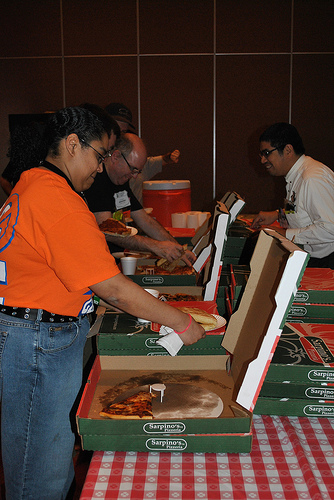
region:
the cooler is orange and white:
[140, 171, 192, 225]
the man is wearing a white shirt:
[256, 118, 332, 259]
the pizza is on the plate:
[96, 215, 138, 239]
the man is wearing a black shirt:
[81, 134, 198, 269]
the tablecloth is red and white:
[74, 408, 332, 498]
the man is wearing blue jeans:
[1, 299, 95, 498]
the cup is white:
[118, 252, 140, 276]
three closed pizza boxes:
[248, 317, 331, 425]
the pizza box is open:
[63, 222, 311, 433]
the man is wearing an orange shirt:
[1, 165, 121, 322]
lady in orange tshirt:
[11, 91, 118, 324]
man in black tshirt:
[98, 131, 166, 228]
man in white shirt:
[252, 113, 333, 261]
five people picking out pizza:
[12, 83, 331, 426]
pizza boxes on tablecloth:
[103, 364, 301, 498]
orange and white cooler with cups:
[140, 176, 215, 233]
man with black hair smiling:
[239, 118, 310, 175]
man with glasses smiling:
[111, 130, 158, 190]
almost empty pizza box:
[104, 366, 244, 453]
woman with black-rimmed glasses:
[25, 104, 118, 192]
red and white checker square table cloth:
[132, 458, 236, 485]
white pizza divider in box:
[143, 379, 175, 400]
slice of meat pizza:
[103, 384, 168, 423]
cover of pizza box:
[222, 224, 313, 406]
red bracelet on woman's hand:
[170, 313, 202, 338]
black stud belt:
[2, 297, 86, 332]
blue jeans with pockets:
[0, 317, 85, 496]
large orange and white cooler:
[142, 169, 199, 228]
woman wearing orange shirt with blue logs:
[1, 158, 116, 311]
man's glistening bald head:
[118, 130, 159, 166]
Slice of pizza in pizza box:
[99, 390, 154, 418]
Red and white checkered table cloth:
[78, 415, 333, 498]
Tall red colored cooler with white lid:
[142, 179, 191, 229]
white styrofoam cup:
[119, 255, 135, 274]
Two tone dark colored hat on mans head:
[104, 100, 135, 131]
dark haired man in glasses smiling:
[251, 121, 332, 267]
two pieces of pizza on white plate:
[98, 217, 137, 237]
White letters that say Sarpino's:
[149, 422, 183, 428]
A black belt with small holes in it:
[0, 303, 93, 323]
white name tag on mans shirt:
[111, 191, 131, 209]